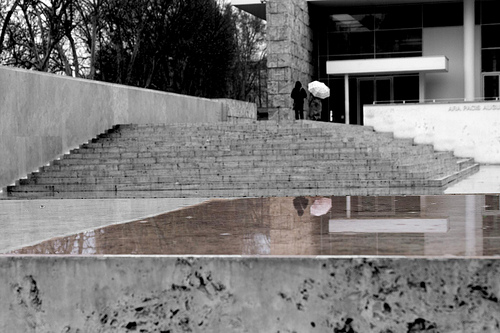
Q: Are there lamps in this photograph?
A: No, there are no lamps.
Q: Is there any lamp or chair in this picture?
A: No, there are no lamps or chairs.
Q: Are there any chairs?
A: No, there are no chairs.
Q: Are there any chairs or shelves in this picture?
A: No, there are no chairs or shelves.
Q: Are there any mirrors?
A: No, there are no mirrors.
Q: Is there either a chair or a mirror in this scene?
A: No, there are no mirrors or chairs.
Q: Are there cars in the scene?
A: No, there are no cars.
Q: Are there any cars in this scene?
A: No, there are no cars.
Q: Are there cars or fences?
A: No, there are no cars or fences.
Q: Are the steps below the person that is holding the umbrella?
A: Yes, the steps are below the person.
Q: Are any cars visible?
A: No, there are no cars.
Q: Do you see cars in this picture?
A: No, there are no cars.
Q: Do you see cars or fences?
A: No, there are no cars or fences.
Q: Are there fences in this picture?
A: No, there are no fences.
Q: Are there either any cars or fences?
A: No, there are no fences or cars.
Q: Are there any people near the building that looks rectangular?
A: Yes, there is a person near the building.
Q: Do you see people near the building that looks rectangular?
A: Yes, there is a person near the building.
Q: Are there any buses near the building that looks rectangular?
A: No, there is a person near the building.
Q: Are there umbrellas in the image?
A: Yes, there is an umbrella.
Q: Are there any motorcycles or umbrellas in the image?
A: Yes, there is an umbrella.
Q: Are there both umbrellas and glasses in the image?
A: No, there is an umbrella but no glasses.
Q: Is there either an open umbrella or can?
A: Yes, there is an open umbrella.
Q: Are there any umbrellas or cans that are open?
A: Yes, the umbrella is open.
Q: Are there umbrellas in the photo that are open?
A: Yes, there is an open umbrella.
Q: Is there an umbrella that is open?
A: Yes, there is an umbrella that is open.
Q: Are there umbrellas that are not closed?
A: Yes, there is a open umbrella.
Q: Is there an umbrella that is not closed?
A: Yes, there is a open umbrella.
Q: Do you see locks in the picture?
A: No, there are no locks.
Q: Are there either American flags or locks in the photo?
A: No, there are no locks or American flags.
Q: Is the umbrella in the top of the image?
A: Yes, the umbrella is in the top of the image.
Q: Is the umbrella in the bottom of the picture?
A: No, the umbrella is in the top of the image.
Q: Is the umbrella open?
A: Yes, the umbrella is open.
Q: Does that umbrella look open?
A: Yes, the umbrella is open.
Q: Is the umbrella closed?
A: No, the umbrella is open.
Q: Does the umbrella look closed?
A: No, the umbrella is open.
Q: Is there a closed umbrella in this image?
A: No, there is an umbrella but it is open.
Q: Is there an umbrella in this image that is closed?
A: No, there is an umbrella but it is open.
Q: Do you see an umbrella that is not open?
A: No, there is an umbrella but it is open.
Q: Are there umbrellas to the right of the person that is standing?
A: Yes, there is an umbrella to the right of the person.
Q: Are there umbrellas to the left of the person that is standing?
A: No, the umbrella is to the right of the person.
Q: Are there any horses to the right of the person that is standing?
A: No, there is an umbrella to the right of the person.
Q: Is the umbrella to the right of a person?
A: Yes, the umbrella is to the right of a person.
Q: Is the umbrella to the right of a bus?
A: No, the umbrella is to the right of a person.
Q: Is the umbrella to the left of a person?
A: No, the umbrella is to the right of a person.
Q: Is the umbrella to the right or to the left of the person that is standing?
A: The umbrella is to the right of the person.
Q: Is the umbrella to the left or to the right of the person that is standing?
A: The umbrella is to the right of the person.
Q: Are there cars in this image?
A: No, there are no cars.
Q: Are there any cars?
A: No, there are no cars.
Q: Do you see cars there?
A: No, there are no cars.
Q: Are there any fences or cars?
A: No, there are no cars or fences.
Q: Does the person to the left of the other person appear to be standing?
A: Yes, the person is standing.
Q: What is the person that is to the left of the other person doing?
A: The person is standing.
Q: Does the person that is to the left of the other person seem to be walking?
A: No, the person is standing.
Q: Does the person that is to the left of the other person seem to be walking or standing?
A: The person is standing.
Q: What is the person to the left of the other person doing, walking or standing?
A: The person is standing.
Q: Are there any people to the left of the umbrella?
A: Yes, there is a person to the left of the umbrella.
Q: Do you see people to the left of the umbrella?
A: Yes, there is a person to the left of the umbrella.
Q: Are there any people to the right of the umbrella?
A: No, the person is to the left of the umbrella.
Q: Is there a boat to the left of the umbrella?
A: No, there is a person to the left of the umbrella.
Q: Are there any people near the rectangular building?
A: Yes, there is a person near the building.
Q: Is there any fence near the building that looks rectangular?
A: No, there is a person near the building.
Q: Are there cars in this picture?
A: No, there are no cars.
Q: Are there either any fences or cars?
A: No, there are no cars or fences.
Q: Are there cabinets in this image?
A: No, there are no cabinets.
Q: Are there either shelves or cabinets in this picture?
A: No, there are no cabinets or shelves.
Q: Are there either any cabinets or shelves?
A: No, there are no cabinets or shelves.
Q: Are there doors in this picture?
A: Yes, there is a door.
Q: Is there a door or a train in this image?
A: Yes, there is a door.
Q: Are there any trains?
A: No, there are no trains.